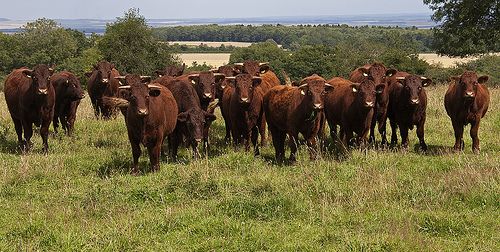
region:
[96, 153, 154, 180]
Shadow of a cow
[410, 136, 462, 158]
Shadow in the field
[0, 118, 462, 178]
Shadows from the cows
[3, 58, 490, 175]
The front of a herd of cows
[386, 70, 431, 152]
Cow with two horns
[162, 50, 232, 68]
Field with nothing growing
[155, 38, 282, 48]
Field full of dead grass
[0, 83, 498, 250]
Sun shining on a grassy field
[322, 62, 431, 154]
Three cows standing together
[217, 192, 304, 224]
Mound of very green grass in a lump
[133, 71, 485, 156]
brown hairly cattle standing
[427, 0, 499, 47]
tree branches hanging overhead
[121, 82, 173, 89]
short and sharp pointed horns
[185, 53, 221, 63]
brown fields in the ranch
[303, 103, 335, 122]
the cow is chewing a large leaf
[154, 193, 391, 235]
green and brown grass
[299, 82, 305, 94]
name tag on the cows ear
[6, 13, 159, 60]
large wide trees behind the cow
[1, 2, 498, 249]
the scene is at a ranch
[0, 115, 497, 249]
grass pasture going to seed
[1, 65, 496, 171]
herd of cattle grazing on grass pasture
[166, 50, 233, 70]
field of dried grass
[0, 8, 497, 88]
line of trees beside pasture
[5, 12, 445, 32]
distant hills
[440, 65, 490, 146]
solitary cow near the herd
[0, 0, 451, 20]
blue-gray hazy sky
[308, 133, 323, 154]
grass seed heads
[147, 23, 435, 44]
line of windbreak trees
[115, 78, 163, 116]
head of coe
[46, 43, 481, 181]
group of cows focused on the camera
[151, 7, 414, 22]
a blue color sky with clouds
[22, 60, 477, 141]
all the cows are brown color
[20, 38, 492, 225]
cows are standing in the ground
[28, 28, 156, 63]
trees with branches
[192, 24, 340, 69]
dirt between the trees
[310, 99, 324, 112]
mouth of the cow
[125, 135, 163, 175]
leg of the cow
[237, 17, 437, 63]
lot of trees in the forest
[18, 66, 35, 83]
ear of the cow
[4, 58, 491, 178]
Herd of cows standing together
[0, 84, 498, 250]
Field full of green grass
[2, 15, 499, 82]
Trees with fields in between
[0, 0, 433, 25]
Overcast, gray sky above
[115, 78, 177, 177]
Cow with two horns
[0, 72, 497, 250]
Grass for cows to eat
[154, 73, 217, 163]
Cow eating the grass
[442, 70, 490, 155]
Cow standing away from other cows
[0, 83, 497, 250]
Tall, green, uncut grass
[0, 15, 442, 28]
Land far off in the distance